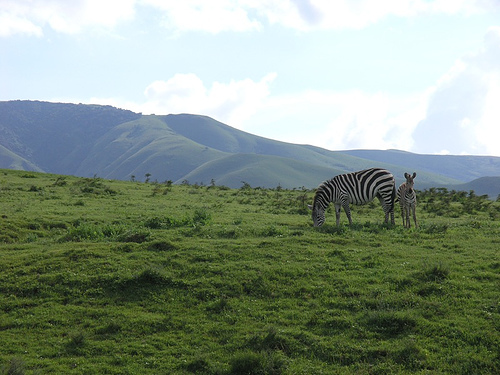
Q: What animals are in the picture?
A: Zebras.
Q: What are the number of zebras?
A: 2.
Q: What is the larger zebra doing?
A: Eating grass.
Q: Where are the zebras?
A: Field.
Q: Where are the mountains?
A: Background.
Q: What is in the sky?
A: Clouds.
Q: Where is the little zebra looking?
A: Towards camera.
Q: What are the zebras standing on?
A: Grass.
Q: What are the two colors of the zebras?
A: Black and white.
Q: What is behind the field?
A: Mountains.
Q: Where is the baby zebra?
A: Behind adult.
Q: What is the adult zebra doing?
A: Eating.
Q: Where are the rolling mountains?
A: Background.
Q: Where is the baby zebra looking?
A: Toward camera.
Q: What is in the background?
A: Mountains.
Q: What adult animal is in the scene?
A: Zebra.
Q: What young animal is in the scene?
A: Zebra.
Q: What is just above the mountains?
A: Clouds on the right.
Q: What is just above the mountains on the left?
A: Sky.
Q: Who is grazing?
A: Adult giraffe.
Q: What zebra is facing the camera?
A: Young one.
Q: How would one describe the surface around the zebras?
A: Lush grass.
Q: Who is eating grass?
A: Zebra.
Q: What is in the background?
A: A rolling green mountain.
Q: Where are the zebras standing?
A: In a grassy green field.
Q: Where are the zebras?
A: On a grassy field.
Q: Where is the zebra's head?
A: Down in the grass.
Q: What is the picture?
A: Zebras.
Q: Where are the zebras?
A: Field.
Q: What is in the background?
A: Mountains.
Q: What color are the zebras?
A: Black and white.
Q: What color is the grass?
A: Green.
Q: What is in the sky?
A: Clouds.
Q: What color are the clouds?
A: White.